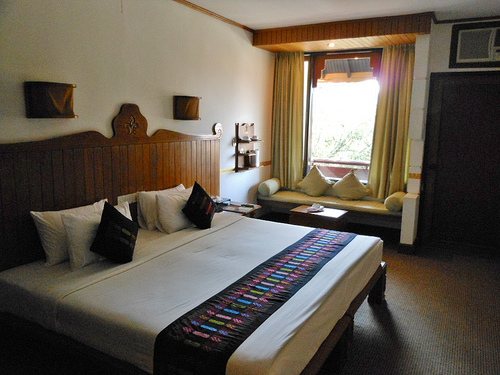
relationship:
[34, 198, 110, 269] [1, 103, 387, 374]
pillow on bed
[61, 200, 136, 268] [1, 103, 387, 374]
pillow on bed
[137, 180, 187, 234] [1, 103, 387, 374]
pillow on bed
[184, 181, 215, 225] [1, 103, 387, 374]
pillow on bed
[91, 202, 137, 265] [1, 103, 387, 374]
pillow on bed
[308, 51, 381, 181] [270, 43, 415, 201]
window has curtain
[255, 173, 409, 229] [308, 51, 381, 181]
sofa under window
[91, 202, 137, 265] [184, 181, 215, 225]
pillow propped up with pillow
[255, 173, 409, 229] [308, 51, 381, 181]
sofa by window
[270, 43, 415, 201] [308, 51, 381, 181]
curtain pushed back from window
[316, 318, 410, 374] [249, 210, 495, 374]
shadow spread on carpet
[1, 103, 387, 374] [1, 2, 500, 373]
bed in hotel room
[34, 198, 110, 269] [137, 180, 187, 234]
pillow on bed next to pillow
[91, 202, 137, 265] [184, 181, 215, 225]
pillow on bed next to pillow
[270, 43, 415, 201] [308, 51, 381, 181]
curtain hanging on window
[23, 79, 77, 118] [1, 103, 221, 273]
light above headboard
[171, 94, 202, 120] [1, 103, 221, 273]
light above headboard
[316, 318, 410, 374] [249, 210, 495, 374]
shadow on carpet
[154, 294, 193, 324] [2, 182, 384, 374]
wrinkle on sheet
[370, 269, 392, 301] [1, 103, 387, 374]
leg on bed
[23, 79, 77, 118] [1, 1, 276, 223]
light on wall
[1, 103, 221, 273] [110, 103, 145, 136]
headboard has decorative edge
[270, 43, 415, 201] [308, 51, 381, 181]
curtain on window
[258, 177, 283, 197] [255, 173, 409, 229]
divan sitting on sofa